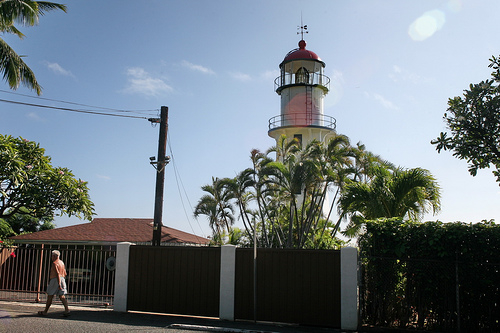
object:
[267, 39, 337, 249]
lighthouse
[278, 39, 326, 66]
roof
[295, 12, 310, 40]
weather vane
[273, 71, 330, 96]
balcony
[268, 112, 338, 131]
railing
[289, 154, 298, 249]
palm trees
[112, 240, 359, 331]
gate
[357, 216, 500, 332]
hedge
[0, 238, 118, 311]
gate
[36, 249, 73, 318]
person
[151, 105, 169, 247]
pole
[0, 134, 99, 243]
tree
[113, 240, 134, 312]
posts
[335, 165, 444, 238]
tree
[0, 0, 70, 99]
tree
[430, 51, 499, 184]
tree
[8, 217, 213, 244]
roof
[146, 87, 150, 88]
clouds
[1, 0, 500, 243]
sky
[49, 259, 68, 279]
shirt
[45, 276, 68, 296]
shorts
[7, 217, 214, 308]
building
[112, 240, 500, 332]
fence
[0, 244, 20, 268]
something